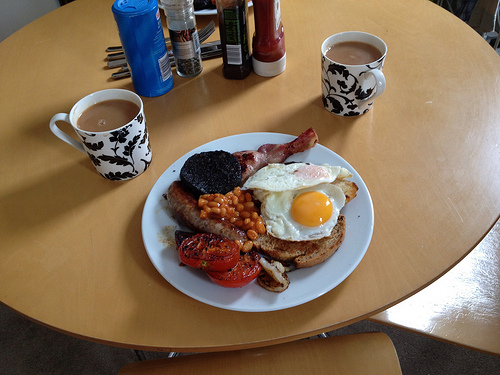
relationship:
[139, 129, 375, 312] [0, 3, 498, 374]
plate on top of table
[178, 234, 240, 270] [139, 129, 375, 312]
tomato on plate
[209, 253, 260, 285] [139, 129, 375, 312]
tomato on plate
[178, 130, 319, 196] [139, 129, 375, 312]
sausage on plate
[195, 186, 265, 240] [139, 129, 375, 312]
beans are on plate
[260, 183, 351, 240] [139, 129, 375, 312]
egg on plate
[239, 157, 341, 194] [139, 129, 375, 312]
egg on plate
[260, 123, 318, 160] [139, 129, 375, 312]
bacon on plate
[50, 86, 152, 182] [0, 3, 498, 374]
cup on top of table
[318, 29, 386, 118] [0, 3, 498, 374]
cup on top of table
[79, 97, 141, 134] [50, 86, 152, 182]
coffee inside cup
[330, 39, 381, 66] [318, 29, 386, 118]
coffee inside cup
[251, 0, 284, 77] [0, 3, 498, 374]
ketchup on top of table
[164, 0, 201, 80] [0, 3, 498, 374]
pepper on table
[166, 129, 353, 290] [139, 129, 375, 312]
food on plate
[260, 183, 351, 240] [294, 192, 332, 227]
egg have yolk up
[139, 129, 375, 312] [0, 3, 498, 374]
plate on table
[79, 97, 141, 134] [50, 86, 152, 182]
coffee in cup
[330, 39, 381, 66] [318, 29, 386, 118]
coffee in cup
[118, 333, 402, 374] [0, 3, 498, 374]
chair sitting by table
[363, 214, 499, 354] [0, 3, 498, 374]
chair sitting by table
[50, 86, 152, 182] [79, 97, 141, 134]
cup of coffee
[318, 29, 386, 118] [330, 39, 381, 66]
cup of coffee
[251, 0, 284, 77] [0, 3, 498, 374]
ketchup on table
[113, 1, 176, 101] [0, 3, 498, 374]
salt shaker on table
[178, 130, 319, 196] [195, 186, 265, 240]
sausage next to beans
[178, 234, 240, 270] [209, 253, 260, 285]
tomato on top of tomato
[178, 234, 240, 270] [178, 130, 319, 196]
tomato next to sausage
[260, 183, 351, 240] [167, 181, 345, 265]
egg on top of toast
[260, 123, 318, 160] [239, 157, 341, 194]
bacon next to egg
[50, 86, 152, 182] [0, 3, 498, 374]
cup on table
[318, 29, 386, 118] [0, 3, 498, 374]
cup on table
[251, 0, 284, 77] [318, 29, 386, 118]
ketchup near cup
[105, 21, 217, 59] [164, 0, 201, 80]
fork behind pepper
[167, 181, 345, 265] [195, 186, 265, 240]
toast by beans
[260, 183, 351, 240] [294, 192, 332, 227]
egg has yolk up